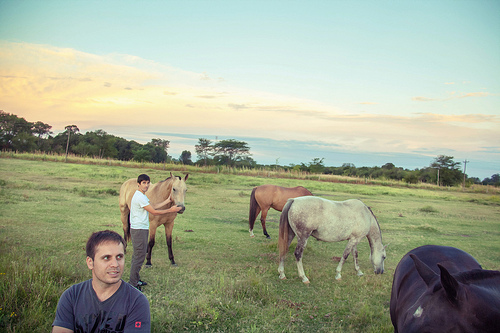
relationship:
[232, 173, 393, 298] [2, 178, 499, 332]
two horses in grass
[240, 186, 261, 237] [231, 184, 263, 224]
hair on tail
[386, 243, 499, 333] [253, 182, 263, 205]
horse has backside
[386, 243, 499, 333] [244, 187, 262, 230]
horse has tail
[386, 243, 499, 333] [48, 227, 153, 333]
horse staring at man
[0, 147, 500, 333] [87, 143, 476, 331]
grass on ground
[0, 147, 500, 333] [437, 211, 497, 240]
grass on ground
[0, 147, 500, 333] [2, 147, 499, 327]
grass on ground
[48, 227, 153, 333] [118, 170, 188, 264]
man standing by horse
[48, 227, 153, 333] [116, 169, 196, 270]
man touching horse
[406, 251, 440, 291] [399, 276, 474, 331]
ear on top of head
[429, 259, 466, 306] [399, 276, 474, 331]
ear on top of head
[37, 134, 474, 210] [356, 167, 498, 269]
grass on ground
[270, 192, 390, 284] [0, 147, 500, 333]
horse eats grass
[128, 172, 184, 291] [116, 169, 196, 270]
man pets horse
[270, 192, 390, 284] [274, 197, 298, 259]
horse has tail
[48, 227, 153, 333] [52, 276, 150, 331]
man wearing shirt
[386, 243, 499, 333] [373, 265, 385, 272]
horse has snout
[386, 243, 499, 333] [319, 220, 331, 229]
horse has snout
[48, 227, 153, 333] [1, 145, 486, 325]
man on field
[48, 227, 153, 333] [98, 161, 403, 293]
man near horses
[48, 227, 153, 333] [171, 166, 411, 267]
man near horse